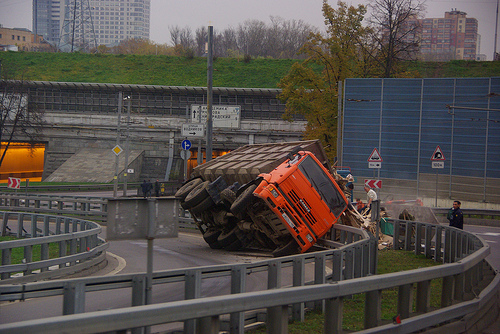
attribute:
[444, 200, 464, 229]
person — standing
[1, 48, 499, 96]
grass — green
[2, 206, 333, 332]
road — grey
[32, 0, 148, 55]
building — white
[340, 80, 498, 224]
fence — grey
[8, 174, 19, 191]
sign — orange, white, arrow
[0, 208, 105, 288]
railing — metal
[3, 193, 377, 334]
railing — metal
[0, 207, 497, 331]
railing — metal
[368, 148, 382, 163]
sign — triangle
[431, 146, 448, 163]
sign — triangle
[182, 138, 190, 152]
sign — blue, white, arrow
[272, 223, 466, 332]
grass — green 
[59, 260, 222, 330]
rails — road 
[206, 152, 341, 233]
truck — orange 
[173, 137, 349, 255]
truck — orange, brown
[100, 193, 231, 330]
road — Gray 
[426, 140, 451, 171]
sign — road 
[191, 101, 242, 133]
sign — road 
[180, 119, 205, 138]
sign — road 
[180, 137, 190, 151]
sign — road 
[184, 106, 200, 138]
arrows — black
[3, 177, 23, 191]
warning sign — sharp turn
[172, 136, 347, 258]
lorry — overturned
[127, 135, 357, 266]
truck — overturned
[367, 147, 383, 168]
triangle sign — white , yellow 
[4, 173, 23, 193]
arrow board — white  , red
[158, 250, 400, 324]
rails — guard rails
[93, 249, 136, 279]
lines — white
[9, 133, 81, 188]
tunnel — underpass 